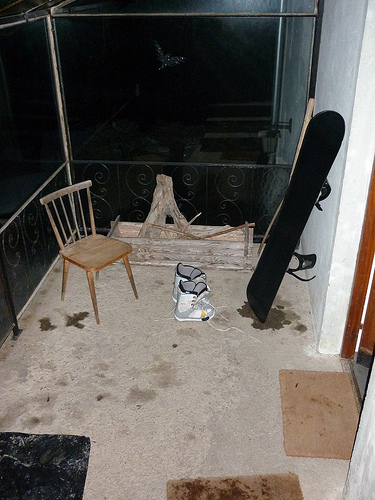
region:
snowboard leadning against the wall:
[195, 72, 348, 320]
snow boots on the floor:
[167, 243, 239, 342]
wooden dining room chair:
[31, 178, 145, 321]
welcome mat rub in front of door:
[281, 356, 356, 459]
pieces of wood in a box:
[133, 167, 254, 247]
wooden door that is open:
[353, 216, 372, 361]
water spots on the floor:
[276, 310, 287, 327]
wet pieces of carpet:
[157, 469, 300, 499]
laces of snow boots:
[199, 303, 253, 337]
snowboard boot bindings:
[288, 250, 318, 284]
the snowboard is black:
[232, 111, 327, 380]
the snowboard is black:
[260, 108, 338, 481]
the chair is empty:
[10, 166, 182, 349]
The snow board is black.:
[227, 109, 344, 331]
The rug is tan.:
[275, 363, 358, 466]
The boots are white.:
[170, 263, 205, 320]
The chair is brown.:
[37, 180, 138, 317]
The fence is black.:
[4, 4, 301, 208]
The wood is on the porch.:
[98, 169, 257, 266]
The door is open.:
[337, 197, 373, 395]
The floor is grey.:
[17, 221, 340, 499]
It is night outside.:
[3, 6, 305, 308]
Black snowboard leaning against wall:
[244, 107, 347, 322]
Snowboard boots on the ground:
[170, 261, 214, 323]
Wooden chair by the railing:
[37, 179, 139, 327]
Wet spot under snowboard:
[236, 297, 290, 333]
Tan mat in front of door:
[279, 369, 360, 457]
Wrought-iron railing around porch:
[0, 161, 294, 336]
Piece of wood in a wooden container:
[108, 174, 254, 271]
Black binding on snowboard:
[288, 245, 316, 283]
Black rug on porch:
[0, 429, 92, 497]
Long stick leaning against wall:
[259, 94, 315, 246]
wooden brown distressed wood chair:
[37, 176, 143, 323]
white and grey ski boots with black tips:
[173, 262, 214, 324]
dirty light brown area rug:
[278, 366, 360, 458]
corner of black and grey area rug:
[2, 432, 90, 499]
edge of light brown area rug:
[162, 472, 305, 499]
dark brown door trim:
[340, 154, 373, 361]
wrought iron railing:
[68, 157, 289, 241]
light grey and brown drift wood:
[139, 172, 195, 238]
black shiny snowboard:
[245, 110, 345, 323]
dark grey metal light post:
[256, 2, 290, 165]